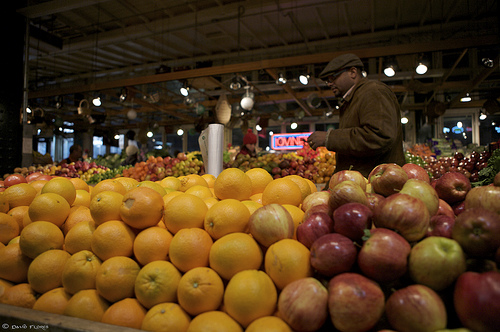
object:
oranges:
[5, 181, 38, 207]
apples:
[397, 174, 443, 217]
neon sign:
[270, 131, 313, 151]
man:
[306, 52, 407, 191]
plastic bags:
[204, 123, 224, 176]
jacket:
[325, 79, 405, 171]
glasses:
[323, 71, 349, 83]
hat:
[318, 53, 361, 78]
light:
[92, 98, 101, 106]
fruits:
[250, 199, 298, 241]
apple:
[386, 285, 445, 331]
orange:
[210, 233, 264, 280]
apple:
[333, 202, 372, 240]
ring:
[308, 139, 315, 145]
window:
[441, 108, 479, 148]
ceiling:
[0, 1, 500, 113]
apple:
[410, 238, 465, 287]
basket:
[74, 99, 91, 116]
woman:
[239, 127, 259, 159]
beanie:
[240, 127, 259, 143]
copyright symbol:
[0, 319, 79, 332]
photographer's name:
[10, 317, 62, 327]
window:
[32, 136, 74, 164]